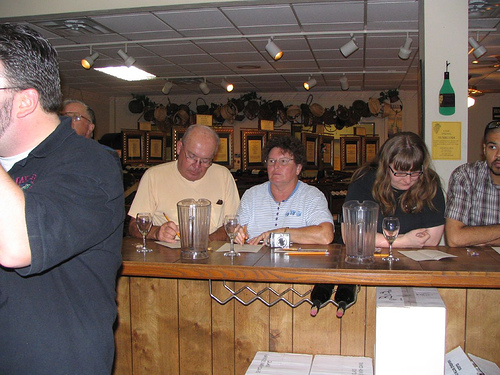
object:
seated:
[128, 124, 247, 244]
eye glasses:
[176, 149, 214, 167]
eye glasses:
[265, 154, 295, 169]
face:
[265, 145, 295, 186]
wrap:
[241, 347, 313, 375]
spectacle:
[0, 0, 499, 374]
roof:
[0, 0, 420, 94]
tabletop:
[122, 241, 500, 273]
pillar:
[424, 0, 473, 246]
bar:
[120, 261, 500, 289]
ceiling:
[0, 0, 499, 97]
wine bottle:
[333, 284, 355, 319]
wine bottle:
[307, 284, 334, 316]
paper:
[153, 240, 180, 250]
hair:
[0, 22, 60, 110]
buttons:
[274, 217, 278, 221]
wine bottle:
[437, 72, 455, 116]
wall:
[424, 0, 469, 205]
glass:
[220, 214, 242, 259]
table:
[110, 237, 499, 374]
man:
[126, 122, 240, 242]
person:
[338, 131, 448, 247]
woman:
[230, 134, 334, 244]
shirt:
[125, 161, 239, 241]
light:
[77, 49, 96, 68]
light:
[115, 46, 137, 65]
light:
[263, 37, 283, 60]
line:
[55, 27, 421, 51]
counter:
[119, 242, 499, 288]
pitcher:
[175, 196, 213, 260]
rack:
[206, 282, 360, 309]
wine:
[309, 285, 333, 317]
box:
[373, 286, 447, 372]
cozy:
[435, 71, 454, 116]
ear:
[13, 87, 40, 120]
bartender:
[0, 20, 127, 374]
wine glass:
[134, 212, 156, 253]